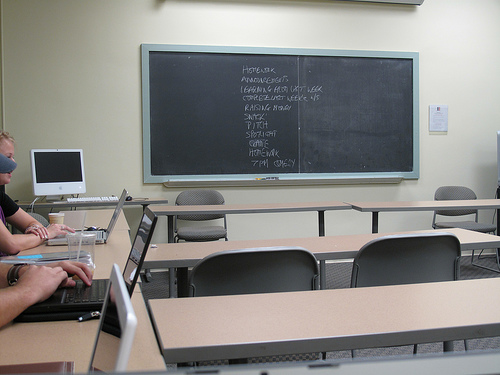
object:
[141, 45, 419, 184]
chalkboard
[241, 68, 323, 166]
writing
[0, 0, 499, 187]
wall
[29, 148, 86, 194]
computer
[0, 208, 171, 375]
desk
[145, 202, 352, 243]
table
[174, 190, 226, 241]
chair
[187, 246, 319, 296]
chairs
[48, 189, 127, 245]
laptop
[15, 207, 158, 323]
computer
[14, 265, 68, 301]
hands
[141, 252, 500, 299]
floor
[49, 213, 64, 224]
cup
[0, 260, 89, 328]
people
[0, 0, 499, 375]
classroom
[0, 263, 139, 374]
laptops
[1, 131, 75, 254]
person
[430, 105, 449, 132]
paper